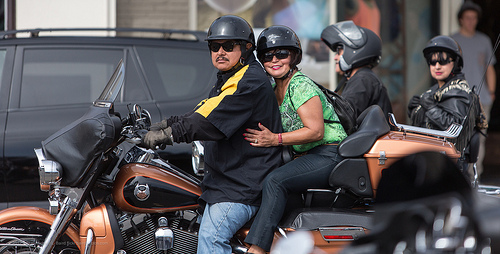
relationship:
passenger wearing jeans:
[237, 23, 358, 253] [240, 141, 345, 250]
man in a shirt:
[140, 17, 280, 244] [170, 61, 289, 208]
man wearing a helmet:
[140, 17, 280, 244] [205, 11, 256, 40]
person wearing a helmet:
[406, 32, 483, 164] [417, 29, 463, 56]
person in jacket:
[406, 32, 483, 164] [408, 80, 485, 168]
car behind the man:
[4, 23, 233, 194] [140, 17, 280, 244]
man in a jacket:
[320, 15, 393, 132] [336, 72, 391, 139]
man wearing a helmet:
[320, 15, 393, 132] [317, 19, 382, 69]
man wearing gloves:
[140, 17, 280, 244] [140, 128, 171, 147]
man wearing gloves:
[140, 17, 280, 244] [148, 115, 168, 126]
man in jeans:
[140, 17, 280, 244] [192, 208, 252, 244]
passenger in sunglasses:
[237, 23, 358, 253] [261, 47, 291, 64]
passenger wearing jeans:
[237, 23, 358, 253] [242, 142, 343, 240]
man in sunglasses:
[140, 14, 281, 245] [210, 37, 239, 54]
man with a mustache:
[140, 14, 281, 245] [215, 53, 231, 63]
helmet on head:
[203, 13, 255, 43] [205, 14, 255, 66]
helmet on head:
[314, 18, 383, 71] [321, 43, 372, 78]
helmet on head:
[421, 34, 473, 61] [426, 51, 471, 81]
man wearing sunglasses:
[140, 14, 281, 245] [201, 36, 256, 62]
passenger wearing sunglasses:
[237, 23, 358, 253] [262, 43, 295, 65]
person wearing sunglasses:
[406, 32, 488, 172] [421, 49, 459, 69]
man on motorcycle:
[140, 14, 281, 245] [3, 101, 485, 251]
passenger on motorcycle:
[237, 23, 358, 253] [0, 65, 488, 252]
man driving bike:
[140, 14, 281, 245] [0, 101, 499, 252]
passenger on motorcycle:
[237, 23, 358, 253] [2, 44, 484, 253]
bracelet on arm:
[270, 127, 285, 152] [241, 79, 325, 148]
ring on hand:
[253, 134, 262, 148] [237, 123, 280, 153]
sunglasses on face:
[206, 40, 239, 60] [208, 35, 248, 72]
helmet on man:
[203, 13, 258, 45] [140, 14, 281, 245]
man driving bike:
[140, 14, 281, 245] [7, 55, 494, 252]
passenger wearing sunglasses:
[237, 23, 358, 253] [259, 45, 299, 64]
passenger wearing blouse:
[237, 23, 358, 253] [272, 71, 348, 153]